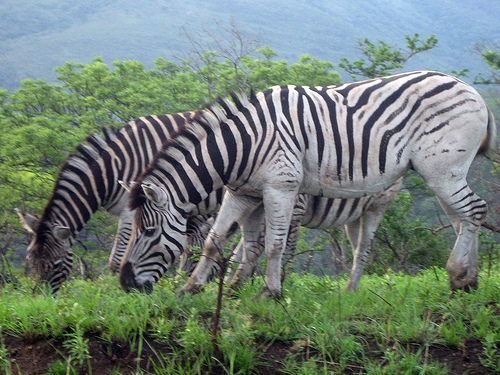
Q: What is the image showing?
A: It is showing a field.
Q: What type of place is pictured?
A: It is a field.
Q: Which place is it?
A: It is a field.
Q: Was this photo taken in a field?
A: Yes, it was taken in a field.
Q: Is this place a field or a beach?
A: It is a field.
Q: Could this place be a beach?
A: No, it is a field.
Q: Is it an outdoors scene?
A: Yes, it is outdoors.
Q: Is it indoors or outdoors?
A: It is outdoors.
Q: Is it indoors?
A: No, it is outdoors.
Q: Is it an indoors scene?
A: No, it is outdoors.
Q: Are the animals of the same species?
A: Yes, all the animals are zebras.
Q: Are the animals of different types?
A: No, all the animals are zebras.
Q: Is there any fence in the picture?
A: No, there are no fences.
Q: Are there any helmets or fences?
A: No, there are no fences or helmets.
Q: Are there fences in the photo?
A: No, there are no fences.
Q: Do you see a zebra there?
A: Yes, there is a zebra.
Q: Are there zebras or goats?
A: Yes, there is a zebra.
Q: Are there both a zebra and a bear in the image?
A: No, there is a zebra but no bears.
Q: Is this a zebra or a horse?
A: This is a zebra.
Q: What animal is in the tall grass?
A: The zebra is in the grass.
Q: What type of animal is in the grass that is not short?
A: The animal is a zebra.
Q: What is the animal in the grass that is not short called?
A: The animal is a zebra.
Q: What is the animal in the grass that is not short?
A: The animal is a zebra.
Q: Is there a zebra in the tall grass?
A: Yes, there is a zebra in the grass.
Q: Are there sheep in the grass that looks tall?
A: No, there is a zebra in the grass.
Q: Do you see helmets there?
A: No, there are no helmets.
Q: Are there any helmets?
A: No, there are no helmets.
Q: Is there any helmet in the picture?
A: No, there are no helmets.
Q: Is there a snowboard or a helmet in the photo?
A: No, there are no helmets or snowboards.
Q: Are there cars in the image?
A: No, there are no cars.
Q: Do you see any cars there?
A: No, there are no cars.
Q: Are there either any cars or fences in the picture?
A: No, there are no cars or fences.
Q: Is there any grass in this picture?
A: Yes, there is grass.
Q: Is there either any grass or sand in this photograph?
A: Yes, there is grass.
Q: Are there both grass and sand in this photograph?
A: No, there is grass but no sand.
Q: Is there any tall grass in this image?
A: Yes, there is tall grass.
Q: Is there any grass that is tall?
A: Yes, there is grass that is tall.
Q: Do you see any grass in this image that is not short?
A: Yes, there is tall grass.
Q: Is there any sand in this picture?
A: No, there is no sand.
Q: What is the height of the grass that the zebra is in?
A: The grass is tall.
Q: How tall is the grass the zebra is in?
A: The grass is tall.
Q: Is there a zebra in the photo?
A: Yes, there are zebras.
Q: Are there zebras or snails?
A: Yes, there are zebras.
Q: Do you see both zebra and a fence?
A: No, there are zebras but no fences.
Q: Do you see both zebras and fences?
A: No, there are zebras but no fences.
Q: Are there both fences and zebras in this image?
A: No, there are zebras but no fences.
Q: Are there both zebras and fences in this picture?
A: No, there are zebras but no fences.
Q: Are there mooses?
A: No, there are no mooses.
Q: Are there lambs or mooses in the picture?
A: No, there are no mooses or lambs.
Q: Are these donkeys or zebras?
A: These are zebras.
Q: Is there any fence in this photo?
A: No, there are no fences.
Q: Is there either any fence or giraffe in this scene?
A: No, there are no fences or giraffes.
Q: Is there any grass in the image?
A: Yes, there is grass.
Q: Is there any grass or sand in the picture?
A: Yes, there is grass.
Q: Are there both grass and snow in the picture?
A: No, there is grass but no snow.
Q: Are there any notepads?
A: No, there are no notepads.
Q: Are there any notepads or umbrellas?
A: No, there are no notepads or umbrellas.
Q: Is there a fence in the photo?
A: No, there are no fences.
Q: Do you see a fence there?
A: No, there are no fences.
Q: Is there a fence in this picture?
A: No, there are no fences.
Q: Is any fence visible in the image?
A: No, there are no fences.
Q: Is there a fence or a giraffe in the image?
A: No, there are no fences or giraffes.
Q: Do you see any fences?
A: No, there are no fences.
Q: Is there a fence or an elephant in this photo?
A: No, there are no fences or elephants.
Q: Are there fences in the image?
A: No, there are no fences.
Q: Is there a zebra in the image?
A: Yes, there is a zebra.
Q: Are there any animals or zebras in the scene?
A: Yes, there is a zebra.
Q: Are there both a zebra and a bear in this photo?
A: No, there is a zebra but no bears.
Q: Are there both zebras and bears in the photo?
A: No, there is a zebra but no bears.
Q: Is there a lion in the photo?
A: No, there are no lions.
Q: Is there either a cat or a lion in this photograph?
A: No, there are no lions or cats.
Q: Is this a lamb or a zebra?
A: This is a zebra.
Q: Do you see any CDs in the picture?
A: No, there are no cds.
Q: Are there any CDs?
A: No, there are no cds.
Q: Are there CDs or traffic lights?
A: No, there are no CDs or traffic lights.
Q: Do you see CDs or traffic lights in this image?
A: No, there are no CDs or traffic lights.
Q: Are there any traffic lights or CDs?
A: No, there are no CDs or traffic lights.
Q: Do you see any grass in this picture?
A: Yes, there is grass.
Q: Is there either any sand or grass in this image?
A: Yes, there is grass.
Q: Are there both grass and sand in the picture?
A: No, there is grass but no sand.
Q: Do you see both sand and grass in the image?
A: No, there is grass but no sand.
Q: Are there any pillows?
A: No, there are no pillows.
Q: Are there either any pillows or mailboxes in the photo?
A: No, there are no pillows or mailboxes.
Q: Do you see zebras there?
A: Yes, there are zebras.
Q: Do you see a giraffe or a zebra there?
A: Yes, there are zebras.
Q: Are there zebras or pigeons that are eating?
A: Yes, the zebras are eating.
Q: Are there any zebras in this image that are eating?
A: Yes, there are zebras that are eating.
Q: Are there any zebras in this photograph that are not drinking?
A: Yes, there are zebras that are eating.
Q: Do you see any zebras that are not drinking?
A: Yes, there are zebras that are eating .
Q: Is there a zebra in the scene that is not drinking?
A: Yes, there are zebras that are eating.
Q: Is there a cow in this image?
A: No, there are no cows.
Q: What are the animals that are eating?
A: The animals are zebras.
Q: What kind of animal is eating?
A: The animal is zebras.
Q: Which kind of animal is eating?
A: The animal is zebras.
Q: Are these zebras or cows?
A: These are zebras.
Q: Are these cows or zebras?
A: These are zebras.